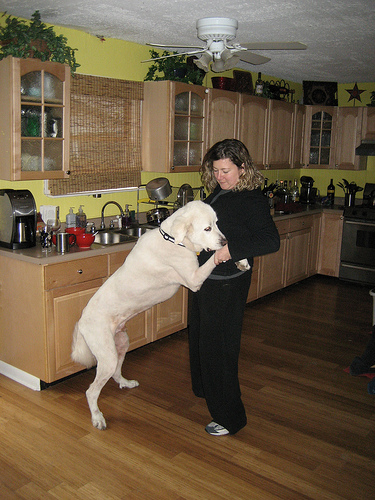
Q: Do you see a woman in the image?
A: Yes, there is a woman.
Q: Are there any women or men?
A: Yes, there is a woman.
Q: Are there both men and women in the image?
A: No, there is a woman but no men.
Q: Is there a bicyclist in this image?
A: No, there are no cyclists.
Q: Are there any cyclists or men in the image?
A: No, there are no cyclists or men.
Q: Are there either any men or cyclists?
A: No, there are no cyclists or men.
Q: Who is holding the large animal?
A: The woman is holding the dog.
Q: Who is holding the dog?
A: The woman is holding the dog.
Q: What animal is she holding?
A: The woman is holding the dog.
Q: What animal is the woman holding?
A: The woman is holding the dog.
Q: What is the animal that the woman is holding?
A: The animal is a dog.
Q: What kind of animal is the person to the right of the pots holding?
A: The woman is holding the dog.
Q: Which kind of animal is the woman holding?
A: The woman is holding the dog.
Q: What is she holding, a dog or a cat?
A: The woman is holding a dog.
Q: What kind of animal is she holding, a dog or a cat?
A: The woman is holding a dog.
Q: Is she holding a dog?
A: Yes, the woman is holding a dog.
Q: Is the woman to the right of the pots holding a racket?
A: No, the woman is holding a dog.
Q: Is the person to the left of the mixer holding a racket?
A: No, the woman is holding a dog.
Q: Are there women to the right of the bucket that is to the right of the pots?
A: Yes, there is a woman to the right of the bucket.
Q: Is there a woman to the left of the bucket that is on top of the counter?
A: No, the woman is to the right of the bucket.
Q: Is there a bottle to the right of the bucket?
A: No, there is a woman to the right of the bucket.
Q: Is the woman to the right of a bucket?
A: Yes, the woman is to the right of a bucket.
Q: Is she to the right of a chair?
A: No, the woman is to the right of a bucket.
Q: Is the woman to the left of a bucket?
A: No, the woman is to the right of a bucket.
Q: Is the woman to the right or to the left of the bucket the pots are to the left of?
A: The woman is to the right of the bucket.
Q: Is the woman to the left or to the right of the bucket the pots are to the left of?
A: The woman is to the right of the bucket.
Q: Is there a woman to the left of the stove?
A: Yes, there is a woman to the left of the stove.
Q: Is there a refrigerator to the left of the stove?
A: No, there is a woman to the left of the stove.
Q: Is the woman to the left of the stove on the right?
A: Yes, the woman is to the left of the stove.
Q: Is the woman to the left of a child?
A: No, the woman is to the left of the stove.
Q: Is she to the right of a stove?
A: No, the woman is to the left of a stove.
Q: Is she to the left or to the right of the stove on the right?
A: The woman is to the left of the stove.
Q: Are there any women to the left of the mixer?
A: Yes, there is a woman to the left of the mixer.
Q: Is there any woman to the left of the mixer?
A: Yes, there is a woman to the left of the mixer.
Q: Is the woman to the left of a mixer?
A: Yes, the woman is to the left of a mixer.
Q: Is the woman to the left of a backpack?
A: No, the woman is to the left of a mixer.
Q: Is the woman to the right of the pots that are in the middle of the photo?
A: Yes, the woman is to the right of the pots.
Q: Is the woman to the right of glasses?
A: No, the woman is to the right of the pots.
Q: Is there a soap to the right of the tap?
A: No, there is a woman to the right of the tap.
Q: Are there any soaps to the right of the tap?
A: No, there is a woman to the right of the tap.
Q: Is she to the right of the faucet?
A: Yes, the woman is to the right of the faucet.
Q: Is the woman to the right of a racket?
A: No, the woman is to the right of the faucet.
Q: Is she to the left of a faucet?
A: No, the woman is to the right of a faucet.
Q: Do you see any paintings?
A: No, there are no paintings.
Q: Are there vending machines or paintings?
A: No, there are no paintings or vending machines.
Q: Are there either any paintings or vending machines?
A: No, there are no paintings or vending machines.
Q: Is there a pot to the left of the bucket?
A: Yes, there are pots to the left of the bucket.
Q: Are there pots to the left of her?
A: Yes, there are pots to the left of the woman.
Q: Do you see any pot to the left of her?
A: Yes, there are pots to the left of the woman.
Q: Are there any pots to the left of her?
A: Yes, there are pots to the left of the woman.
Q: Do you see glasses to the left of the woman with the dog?
A: No, there are pots to the left of the woman.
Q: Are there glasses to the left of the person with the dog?
A: No, there are pots to the left of the woman.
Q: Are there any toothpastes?
A: No, there are no toothpastes.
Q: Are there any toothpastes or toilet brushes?
A: No, there are no toothpastes or toilet brushes.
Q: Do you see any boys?
A: No, there are no boys.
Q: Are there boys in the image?
A: No, there are no boys.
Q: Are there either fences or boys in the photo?
A: No, there are no boys or fences.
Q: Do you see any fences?
A: No, there are no fences.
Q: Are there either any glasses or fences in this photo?
A: No, there are no fences or glasses.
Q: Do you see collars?
A: Yes, there is a collar.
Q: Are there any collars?
A: Yes, there is a collar.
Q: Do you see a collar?
A: Yes, there is a collar.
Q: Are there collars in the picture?
A: Yes, there is a collar.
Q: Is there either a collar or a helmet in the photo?
A: Yes, there is a collar.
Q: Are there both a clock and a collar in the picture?
A: No, there is a collar but no clocks.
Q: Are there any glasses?
A: No, there are no glasses.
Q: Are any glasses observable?
A: No, there are no glasses.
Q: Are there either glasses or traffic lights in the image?
A: No, there are no glasses or traffic lights.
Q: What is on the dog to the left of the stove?
A: The collar is on the dog.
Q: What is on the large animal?
A: The collar is on the dog.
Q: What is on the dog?
A: The collar is on the dog.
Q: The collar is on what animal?
A: The collar is on the dog.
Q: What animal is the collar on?
A: The collar is on the dog.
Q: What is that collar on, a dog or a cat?
A: The collar is on a dog.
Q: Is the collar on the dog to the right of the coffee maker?
A: Yes, the collar is on the dog.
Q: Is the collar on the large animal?
A: Yes, the collar is on the dog.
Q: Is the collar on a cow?
A: No, the collar is on the dog.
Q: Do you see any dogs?
A: Yes, there is a dog.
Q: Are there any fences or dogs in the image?
A: Yes, there is a dog.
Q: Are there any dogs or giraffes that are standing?
A: Yes, the dog is standing.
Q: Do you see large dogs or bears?
A: Yes, there is a large dog.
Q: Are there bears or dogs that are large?
A: Yes, the dog is large.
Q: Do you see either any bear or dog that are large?
A: Yes, the dog is large.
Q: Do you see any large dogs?
A: Yes, there is a large dog.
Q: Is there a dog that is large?
A: Yes, there is a dog that is large.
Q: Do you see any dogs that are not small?
A: Yes, there is a large dog.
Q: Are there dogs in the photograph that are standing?
A: Yes, there is a dog that is standing.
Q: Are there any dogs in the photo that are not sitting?
A: Yes, there is a dog that is standing.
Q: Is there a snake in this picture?
A: No, there are no snakes.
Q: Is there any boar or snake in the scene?
A: No, there are no snakes or boars.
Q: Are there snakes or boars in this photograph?
A: No, there are no snakes or boars.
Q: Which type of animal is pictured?
A: The animal is a dog.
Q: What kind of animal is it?
A: The animal is a dog.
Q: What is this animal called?
A: That is a dog.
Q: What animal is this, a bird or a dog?
A: That is a dog.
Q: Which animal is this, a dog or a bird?
A: That is a dog.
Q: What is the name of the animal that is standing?
A: The animal is a dog.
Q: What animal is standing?
A: The animal is a dog.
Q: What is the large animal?
A: The animal is a dog.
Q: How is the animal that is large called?
A: The animal is a dog.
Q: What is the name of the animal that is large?
A: The animal is a dog.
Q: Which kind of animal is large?
A: The animal is a dog.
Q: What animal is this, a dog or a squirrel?
A: This is a dog.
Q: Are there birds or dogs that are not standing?
A: No, there is a dog but it is standing.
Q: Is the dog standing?
A: Yes, the dog is standing.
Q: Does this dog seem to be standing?
A: Yes, the dog is standing.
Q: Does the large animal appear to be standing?
A: Yes, the dog is standing.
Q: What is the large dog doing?
A: The dog is standing.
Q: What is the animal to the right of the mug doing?
A: The dog is standing.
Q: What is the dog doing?
A: The dog is standing.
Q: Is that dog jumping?
A: No, the dog is standing.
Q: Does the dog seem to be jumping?
A: No, the dog is standing.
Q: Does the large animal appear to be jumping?
A: No, the dog is standing.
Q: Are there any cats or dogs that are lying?
A: No, there is a dog but it is standing.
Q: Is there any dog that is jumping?
A: No, there is a dog but it is standing.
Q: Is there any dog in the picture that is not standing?
A: No, there is a dog but it is standing.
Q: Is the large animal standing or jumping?
A: The dog is standing.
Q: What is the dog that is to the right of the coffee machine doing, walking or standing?
A: The dog is standing.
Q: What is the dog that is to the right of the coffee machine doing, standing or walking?
A: The dog is standing.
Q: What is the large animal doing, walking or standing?
A: The dog is standing.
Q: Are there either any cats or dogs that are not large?
A: No, there is a dog but it is large.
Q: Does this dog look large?
A: Yes, the dog is large.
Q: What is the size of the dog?
A: The dog is large.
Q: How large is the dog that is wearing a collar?
A: The dog is large.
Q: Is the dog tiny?
A: No, the dog is large.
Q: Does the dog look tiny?
A: No, the dog is large.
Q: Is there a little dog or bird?
A: No, there is a dog but it is large.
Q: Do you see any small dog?
A: No, there is a dog but it is large.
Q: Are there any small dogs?
A: No, there is a dog but it is large.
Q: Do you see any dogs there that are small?
A: No, there is a dog but it is large.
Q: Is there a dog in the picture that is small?
A: No, there is a dog but it is large.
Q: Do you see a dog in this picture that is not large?
A: No, there is a dog but it is large.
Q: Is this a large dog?
A: Yes, this is a large dog.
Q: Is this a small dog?
A: No, this is a large dog.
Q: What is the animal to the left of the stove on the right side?
A: The animal is a dog.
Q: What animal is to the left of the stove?
A: The animal is a dog.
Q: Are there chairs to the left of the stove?
A: No, there is a dog to the left of the stove.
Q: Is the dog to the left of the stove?
A: Yes, the dog is to the left of the stove.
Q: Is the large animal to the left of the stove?
A: Yes, the dog is to the left of the stove.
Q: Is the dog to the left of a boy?
A: No, the dog is to the left of the stove.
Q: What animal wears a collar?
A: The dog wears a collar.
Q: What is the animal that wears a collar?
A: The animal is a dog.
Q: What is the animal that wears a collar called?
A: The animal is a dog.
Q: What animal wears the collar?
A: The animal is a dog.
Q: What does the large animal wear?
A: The dog wears a collar.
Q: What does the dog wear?
A: The dog wears a collar.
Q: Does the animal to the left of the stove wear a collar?
A: Yes, the dog wears a collar.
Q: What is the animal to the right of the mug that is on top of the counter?
A: The animal is a dog.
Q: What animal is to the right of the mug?
A: The animal is a dog.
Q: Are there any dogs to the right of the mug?
A: Yes, there is a dog to the right of the mug.